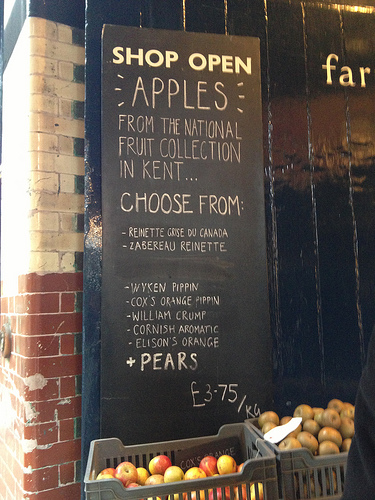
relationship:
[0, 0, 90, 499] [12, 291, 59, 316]
wall made of brick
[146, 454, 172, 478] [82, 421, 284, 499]
apple in bin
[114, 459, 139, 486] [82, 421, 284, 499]
apple in bin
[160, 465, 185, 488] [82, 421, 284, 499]
apple in bin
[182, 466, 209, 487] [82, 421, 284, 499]
apple in bin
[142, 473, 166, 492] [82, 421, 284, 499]
apple in bin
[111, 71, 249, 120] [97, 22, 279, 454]
apples on poster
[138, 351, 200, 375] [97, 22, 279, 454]
pears on board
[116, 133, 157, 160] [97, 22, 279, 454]
fruit on board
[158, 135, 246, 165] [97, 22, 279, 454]
collection on board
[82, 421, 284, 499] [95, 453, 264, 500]
bin holding apples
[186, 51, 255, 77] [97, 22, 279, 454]
open on board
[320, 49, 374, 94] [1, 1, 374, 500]
far on building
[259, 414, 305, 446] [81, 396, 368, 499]
tag between bins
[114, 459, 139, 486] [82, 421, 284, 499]
apple in crate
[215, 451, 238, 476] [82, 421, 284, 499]
apple in crate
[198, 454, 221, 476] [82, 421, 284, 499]
apple in crate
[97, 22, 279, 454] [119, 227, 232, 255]
chalkboard lting apples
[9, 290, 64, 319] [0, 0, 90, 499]
brick in wall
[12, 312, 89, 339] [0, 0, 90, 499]
brick in wall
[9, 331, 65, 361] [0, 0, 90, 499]
brick in wall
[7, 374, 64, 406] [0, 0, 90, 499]
brick in wall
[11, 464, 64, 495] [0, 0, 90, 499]
brick in wall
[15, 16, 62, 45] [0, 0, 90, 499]
brick in wall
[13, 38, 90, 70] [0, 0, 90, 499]
brick in wall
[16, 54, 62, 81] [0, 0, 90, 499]
brick in wall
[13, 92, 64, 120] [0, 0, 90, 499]
brick in wall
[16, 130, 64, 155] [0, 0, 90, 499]
brick in wall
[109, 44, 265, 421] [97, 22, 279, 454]
writing on chalkboard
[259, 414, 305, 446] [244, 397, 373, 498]
sign in crate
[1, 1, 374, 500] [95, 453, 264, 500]
shop selling apples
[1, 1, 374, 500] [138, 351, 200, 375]
shop selling pears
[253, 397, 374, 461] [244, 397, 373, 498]
pears are in crate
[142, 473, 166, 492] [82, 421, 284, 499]
apple in crate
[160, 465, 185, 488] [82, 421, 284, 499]
apple in crate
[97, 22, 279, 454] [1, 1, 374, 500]
sign outside shop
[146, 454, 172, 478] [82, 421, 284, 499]
apple in crate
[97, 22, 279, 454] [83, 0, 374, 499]
sign on wall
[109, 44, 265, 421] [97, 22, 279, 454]
writing on sign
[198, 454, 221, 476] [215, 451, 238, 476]
apple next to apple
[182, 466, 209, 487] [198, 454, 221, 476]
apple next to apple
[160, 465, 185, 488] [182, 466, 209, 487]
apple next to apple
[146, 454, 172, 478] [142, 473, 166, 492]
apple next to apple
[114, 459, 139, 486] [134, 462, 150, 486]
apple next to apple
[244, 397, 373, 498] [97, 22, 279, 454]
crate in front of sign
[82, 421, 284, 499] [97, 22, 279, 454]
crate in front of sign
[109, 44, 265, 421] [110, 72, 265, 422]
words are in chalk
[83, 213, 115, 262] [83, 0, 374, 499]
spot on wall